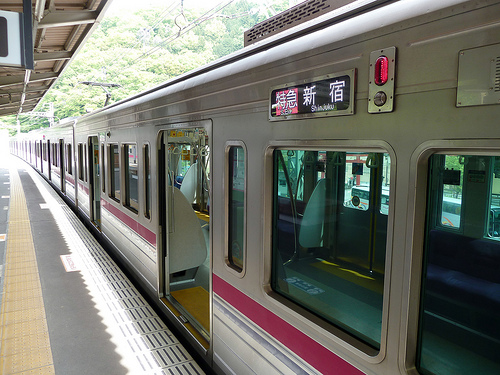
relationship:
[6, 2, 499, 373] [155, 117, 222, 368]
train has door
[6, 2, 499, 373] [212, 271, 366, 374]
train has line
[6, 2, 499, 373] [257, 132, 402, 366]
train has windows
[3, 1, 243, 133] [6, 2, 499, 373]
wires above train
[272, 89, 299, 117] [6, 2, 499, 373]
characters on train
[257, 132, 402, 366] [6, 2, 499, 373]
windows are on train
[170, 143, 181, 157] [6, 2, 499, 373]
hanger straps in train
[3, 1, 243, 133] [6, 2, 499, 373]
wires for train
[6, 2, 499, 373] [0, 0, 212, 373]
train at station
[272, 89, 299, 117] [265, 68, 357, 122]
characters on sign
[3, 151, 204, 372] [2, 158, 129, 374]
floor has shadow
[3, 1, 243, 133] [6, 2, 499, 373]
wires are over train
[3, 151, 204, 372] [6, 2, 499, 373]
floor near train